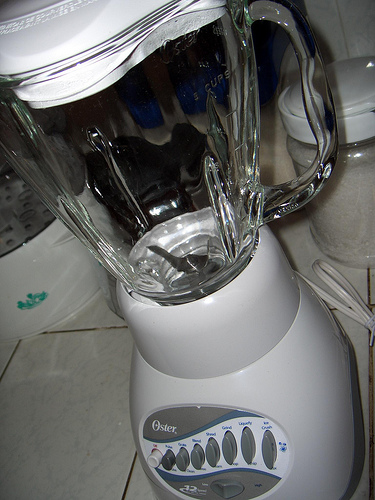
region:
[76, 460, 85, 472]
part of a surface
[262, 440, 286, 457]
part of a button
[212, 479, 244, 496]
part of a switch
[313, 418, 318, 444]
edge of a kettle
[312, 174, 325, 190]
part of an handle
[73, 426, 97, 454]
part of a tile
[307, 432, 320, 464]
side of a jug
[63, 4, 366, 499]
Oster twelve speed blender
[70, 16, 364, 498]
white twelve speed blender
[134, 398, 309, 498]
Oster brand blender push button controls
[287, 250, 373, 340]
white cord to blender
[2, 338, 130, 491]
marble tile appearance countertop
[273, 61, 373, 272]
kitchen storage jar with white contents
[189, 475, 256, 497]
power control for Oster blender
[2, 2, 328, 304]
heavy clear glass pitcher style blender jar with cover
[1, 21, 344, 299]
Oster six cup glass jar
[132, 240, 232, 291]
Oster blender blade cutter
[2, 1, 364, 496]
white oster blender in kitchen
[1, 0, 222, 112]
white blender lid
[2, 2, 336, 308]
glass beaker blender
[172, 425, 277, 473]
small light gray buttons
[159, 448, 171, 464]
dark gray button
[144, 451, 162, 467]
small white button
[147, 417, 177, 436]
white oster symbol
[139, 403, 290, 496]
blue and gray lebel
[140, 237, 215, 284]
gray metal blender blades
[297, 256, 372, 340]
white cable of oster blender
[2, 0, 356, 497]
a white electric blender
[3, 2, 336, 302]
clear glass blender jar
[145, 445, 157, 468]
white push button controller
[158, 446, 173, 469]
grey push button controller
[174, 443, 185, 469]
grey push button controller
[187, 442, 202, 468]
grey push button controller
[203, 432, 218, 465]
grey push button controller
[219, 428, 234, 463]
grey push button controller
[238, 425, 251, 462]
grey push button controller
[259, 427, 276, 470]
grey push button controller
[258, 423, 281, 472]
This is a button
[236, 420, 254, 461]
This is a button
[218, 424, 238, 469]
This is a button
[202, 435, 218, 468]
This is a button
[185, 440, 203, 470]
This is a button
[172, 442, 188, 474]
This is a button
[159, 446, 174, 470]
This is a button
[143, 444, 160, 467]
This is a button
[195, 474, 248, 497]
This is a button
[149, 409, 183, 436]
This is a brand name